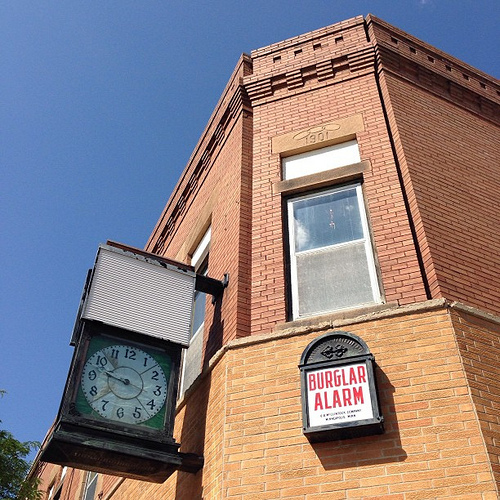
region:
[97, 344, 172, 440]
clock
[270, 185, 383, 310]
window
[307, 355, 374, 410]
red and white sign on building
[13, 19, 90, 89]
white clouds in blue sky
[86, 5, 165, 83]
white clouds in blue sky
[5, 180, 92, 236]
white clouds in blue sky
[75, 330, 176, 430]
green and white clock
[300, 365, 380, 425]
red letters on a sign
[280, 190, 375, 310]
large white window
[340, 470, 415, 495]
brown bricks on wall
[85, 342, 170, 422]
numbers on a clock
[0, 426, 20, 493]
green tree limbs near building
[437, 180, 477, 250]
brown bricks on wall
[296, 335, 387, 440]
large sign with red letters below window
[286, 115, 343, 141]
numbers on brick wall above window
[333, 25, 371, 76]
brown brick triming on wall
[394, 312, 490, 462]
brown building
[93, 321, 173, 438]
black and white clock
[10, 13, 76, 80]
white clouds in blue ski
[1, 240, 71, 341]
white clouds in blue ski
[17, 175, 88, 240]
white clouds in blue ski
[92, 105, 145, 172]
white clouds in blue ski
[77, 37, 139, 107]
white clouds in blue ski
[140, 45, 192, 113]
white clouds in blue ski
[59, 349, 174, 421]
black and white clock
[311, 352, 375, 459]
white and red sign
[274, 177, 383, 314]
window in brown building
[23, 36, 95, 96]
white clouds in blue sky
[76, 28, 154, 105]
white clouds in blue sky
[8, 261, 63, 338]
white clouds in blue sky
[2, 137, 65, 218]
white clouds in blue sky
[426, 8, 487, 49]
white clouds in blue sky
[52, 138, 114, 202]
white clouds in blue sky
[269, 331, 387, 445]
Burglar alarm sign on a building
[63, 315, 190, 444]
Clock on a building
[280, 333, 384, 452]
sign on a building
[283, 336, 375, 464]
Burglar alarm on a building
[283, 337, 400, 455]
Clock on a building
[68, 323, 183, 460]
Green clock on a building